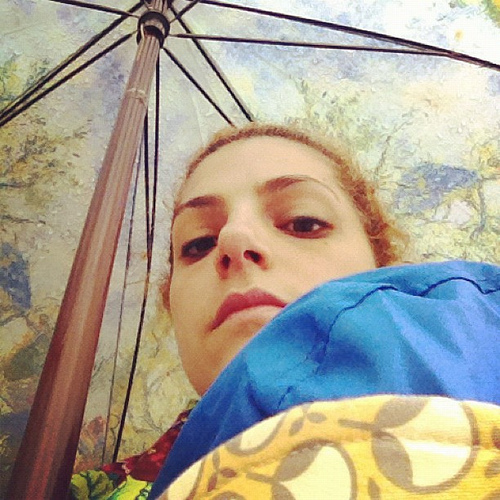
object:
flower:
[287, 401, 327, 438]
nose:
[205, 201, 273, 278]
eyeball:
[293, 216, 314, 234]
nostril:
[242, 248, 266, 269]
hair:
[158, 122, 416, 318]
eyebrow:
[168, 193, 221, 212]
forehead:
[171, 134, 338, 199]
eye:
[271, 209, 334, 241]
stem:
[0, 30, 138, 131]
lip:
[206, 305, 283, 333]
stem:
[162, 30, 450, 60]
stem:
[160, 1, 257, 126]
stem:
[112, 41, 158, 458]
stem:
[1, 0, 145, 125]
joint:
[136, 0, 171, 42]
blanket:
[155, 394, 499, 498]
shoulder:
[267, 259, 499, 338]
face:
[162, 133, 382, 403]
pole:
[0, 0, 168, 500]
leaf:
[369, 430, 416, 493]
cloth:
[137, 260, 500, 500]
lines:
[266, 274, 499, 420]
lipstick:
[209, 286, 288, 332]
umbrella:
[0, 0, 500, 500]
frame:
[162, 2, 452, 58]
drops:
[32, 237, 52, 248]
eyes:
[178, 232, 221, 259]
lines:
[283, 234, 322, 241]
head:
[157, 120, 391, 403]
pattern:
[338, 394, 481, 496]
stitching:
[334, 417, 372, 431]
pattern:
[1, 48, 86, 265]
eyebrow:
[260, 169, 340, 198]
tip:
[218, 224, 246, 250]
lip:
[208, 287, 288, 330]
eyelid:
[276, 213, 336, 228]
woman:
[142, 122, 500, 499]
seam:
[273, 273, 500, 416]